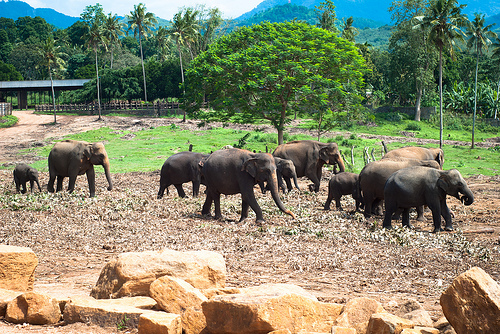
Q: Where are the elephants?
A: At a preserve or zoo.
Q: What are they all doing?
A: Walking.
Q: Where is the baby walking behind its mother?
A: At the back of the group.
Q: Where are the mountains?
A: Behind the trees.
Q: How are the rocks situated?
A: They are piled on each other.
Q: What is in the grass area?
A: A tree.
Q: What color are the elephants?
A: Grayish-tan.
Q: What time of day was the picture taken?
A: Daylight.